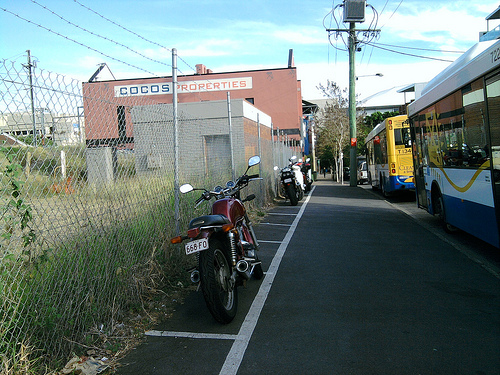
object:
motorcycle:
[171, 155, 265, 325]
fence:
[0, 54, 305, 374]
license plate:
[185, 236, 208, 255]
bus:
[402, 46, 500, 254]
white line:
[212, 184, 315, 374]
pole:
[346, 20, 357, 186]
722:
[489, 48, 499, 63]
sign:
[348, 138, 355, 147]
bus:
[361, 113, 415, 195]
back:
[388, 114, 415, 187]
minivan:
[358, 163, 368, 184]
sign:
[112, 75, 249, 94]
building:
[81, 107, 319, 266]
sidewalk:
[98, 172, 500, 375]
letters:
[119, 83, 173, 97]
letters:
[176, 79, 248, 92]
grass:
[1, 142, 265, 375]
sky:
[0, 1, 498, 112]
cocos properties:
[118, 80, 249, 94]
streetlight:
[350, 71, 386, 77]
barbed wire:
[70, 0, 173, 55]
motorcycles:
[273, 156, 303, 207]